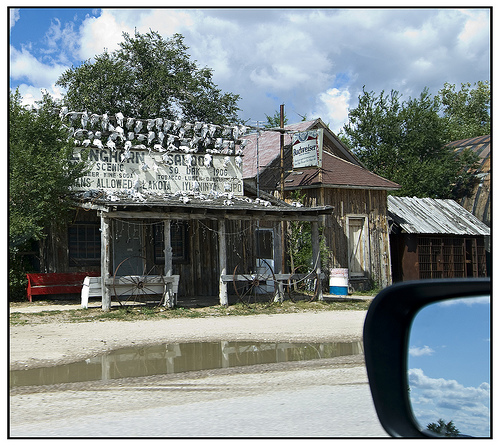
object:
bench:
[24, 271, 101, 303]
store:
[25, 105, 333, 313]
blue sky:
[10, 8, 491, 154]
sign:
[57, 146, 245, 200]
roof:
[55, 190, 336, 217]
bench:
[80, 274, 180, 310]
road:
[11, 296, 390, 437]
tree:
[8, 85, 97, 301]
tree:
[53, 26, 252, 156]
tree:
[258, 109, 352, 152]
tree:
[336, 83, 490, 199]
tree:
[434, 80, 491, 144]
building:
[23, 107, 336, 314]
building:
[234, 115, 404, 302]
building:
[385, 192, 492, 284]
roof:
[386, 195, 491, 235]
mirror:
[362, 275, 492, 437]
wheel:
[232, 255, 277, 311]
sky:
[407, 295, 491, 438]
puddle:
[9, 330, 370, 397]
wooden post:
[279, 104, 285, 303]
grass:
[9, 298, 371, 327]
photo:
[0, 0, 500, 446]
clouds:
[9, 41, 81, 98]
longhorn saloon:
[69, 148, 214, 168]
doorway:
[348, 216, 369, 280]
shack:
[272, 148, 402, 293]